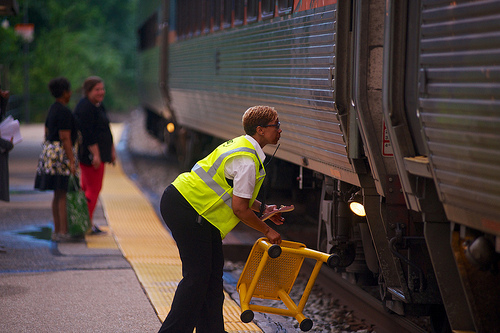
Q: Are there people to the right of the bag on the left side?
A: Yes, there is a person to the right of the bag.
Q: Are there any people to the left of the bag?
A: No, the person is to the right of the bag.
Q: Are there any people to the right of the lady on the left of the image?
A: Yes, there is a person to the right of the lady.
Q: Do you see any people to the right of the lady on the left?
A: Yes, there is a person to the right of the lady.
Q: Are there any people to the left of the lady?
A: No, the person is to the right of the lady.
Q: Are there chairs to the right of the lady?
A: No, there is a person to the right of the lady.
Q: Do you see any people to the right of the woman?
A: Yes, there is a person to the right of the woman.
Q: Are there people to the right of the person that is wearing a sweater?
A: Yes, there is a person to the right of the woman.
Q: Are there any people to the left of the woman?
A: No, the person is to the right of the woman.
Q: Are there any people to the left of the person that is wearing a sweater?
A: No, the person is to the right of the woman.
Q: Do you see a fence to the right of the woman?
A: No, there is a person to the right of the woman.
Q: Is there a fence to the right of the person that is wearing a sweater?
A: No, there is a person to the right of the woman.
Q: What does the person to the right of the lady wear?
A: The person wears a dress.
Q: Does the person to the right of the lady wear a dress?
A: Yes, the person wears a dress.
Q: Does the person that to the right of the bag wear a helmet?
A: No, the person wears a dress.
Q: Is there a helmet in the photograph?
A: No, there are no helmets.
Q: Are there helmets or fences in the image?
A: No, there are no helmets or fences.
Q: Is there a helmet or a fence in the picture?
A: No, there are no helmets or fences.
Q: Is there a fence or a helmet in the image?
A: No, there are no helmets or fences.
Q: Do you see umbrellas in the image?
A: No, there are no umbrellas.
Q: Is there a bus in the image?
A: No, there are no buses.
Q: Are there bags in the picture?
A: Yes, there is a bag.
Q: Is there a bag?
A: Yes, there is a bag.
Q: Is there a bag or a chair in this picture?
A: Yes, there is a bag.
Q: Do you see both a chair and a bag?
A: No, there is a bag but no chairs.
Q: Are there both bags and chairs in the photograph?
A: No, there is a bag but no chairs.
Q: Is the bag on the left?
A: Yes, the bag is on the left of the image.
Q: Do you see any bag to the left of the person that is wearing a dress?
A: Yes, there is a bag to the left of the person.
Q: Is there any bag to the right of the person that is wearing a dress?
A: No, the bag is to the left of the person.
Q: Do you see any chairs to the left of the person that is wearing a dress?
A: No, there is a bag to the left of the person.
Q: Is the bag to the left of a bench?
A: No, the bag is to the left of the person.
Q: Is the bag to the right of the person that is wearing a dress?
A: No, the bag is to the left of the person.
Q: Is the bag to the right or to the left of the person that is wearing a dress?
A: The bag is to the left of the person.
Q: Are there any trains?
A: Yes, there is a train.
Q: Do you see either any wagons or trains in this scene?
A: Yes, there is a train.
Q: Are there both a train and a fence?
A: No, there is a train but no fences.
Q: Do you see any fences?
A: No, there are no fences.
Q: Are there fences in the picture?
A: No, there are no fences.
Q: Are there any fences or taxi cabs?
A: No, there are no fences or taxi cabs.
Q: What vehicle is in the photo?
A: The vehicle is a train.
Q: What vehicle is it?
A: The vehicle is a train.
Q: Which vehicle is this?
A: This is a train.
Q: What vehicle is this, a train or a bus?
A: This is a train.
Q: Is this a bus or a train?
A: This is a train.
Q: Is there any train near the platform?
A: Yes, there is a train near the platform.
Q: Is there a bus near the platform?
A: No, there is a train near the platform.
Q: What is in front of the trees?
A: The train is in front of the trees.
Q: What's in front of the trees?
A: The train is in front of the trees.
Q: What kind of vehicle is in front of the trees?
A: The vehicle is a train.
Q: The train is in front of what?
A: The train is in front of the trees.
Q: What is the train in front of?
A: The train is in front of the trees.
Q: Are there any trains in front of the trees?
A: Yes, there is a train in front of the trees.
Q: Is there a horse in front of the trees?
A: No, there is a train in front of the trees.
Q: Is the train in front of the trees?
A: Yes, the train is in front of the trees.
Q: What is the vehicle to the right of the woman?
A: The vehicle is a train.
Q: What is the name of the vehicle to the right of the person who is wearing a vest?
A: The vehicle is a train.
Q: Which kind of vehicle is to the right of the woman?
A: The vehicle is a train.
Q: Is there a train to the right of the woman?
A: Yes, there is a train to the right of the woman.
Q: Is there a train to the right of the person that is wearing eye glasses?
A: Yes, there is a train to the right of the woman.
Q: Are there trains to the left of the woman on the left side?
A: No, the train is to the right of the woman.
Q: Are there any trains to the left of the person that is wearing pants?
A: No, the train is to the right of the woman.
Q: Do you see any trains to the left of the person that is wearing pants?
A: No, the train is to the right of the woman.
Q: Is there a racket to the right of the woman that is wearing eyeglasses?
A: No, there is a train to the right of the woman.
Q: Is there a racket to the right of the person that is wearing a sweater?
A: No, there is a train to the right of the woman.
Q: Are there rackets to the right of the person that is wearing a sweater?
A: No, there is a train to the right of the woman.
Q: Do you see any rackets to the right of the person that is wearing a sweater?
A: No, there is a train to the right of the woman.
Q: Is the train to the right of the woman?
A: Yes, the train is to the right of the woman.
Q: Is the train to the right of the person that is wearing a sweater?
A: Yes, the train is to the right of the woman.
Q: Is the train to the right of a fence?
A: No, the train is to the right of the woman.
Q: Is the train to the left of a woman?
A: No, the train is to the right of a woman.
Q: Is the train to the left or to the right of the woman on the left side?
A: The train is to the right of the woman.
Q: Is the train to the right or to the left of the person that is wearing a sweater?
A: The train is to the right of the woman.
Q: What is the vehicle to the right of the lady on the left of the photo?
A: The vehicle is a train.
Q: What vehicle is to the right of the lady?
A: The vehicle is a train.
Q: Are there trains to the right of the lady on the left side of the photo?
A: Yes, there is a train to the right of the lady.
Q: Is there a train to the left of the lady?
A: No, the train is to the right of the lady.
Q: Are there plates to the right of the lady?
A: No, there is a train to the right of the lady.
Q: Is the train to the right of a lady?
A: Yes, the train is to the right of a lady.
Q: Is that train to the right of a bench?
A: No, the train is to the right of a lady.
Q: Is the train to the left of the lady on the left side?
A: No, the train is to the right of the lady.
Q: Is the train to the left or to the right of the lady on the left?
A: The train is to the right of the lady.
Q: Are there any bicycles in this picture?
A: No, there are no bicycles.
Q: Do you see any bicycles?
A: No, there are no bicycles.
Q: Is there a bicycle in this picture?
A: No, there are no bicycles.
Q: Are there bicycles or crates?
A: No, there are no bicycles or crates.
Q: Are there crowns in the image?
A: No, there are no crowns.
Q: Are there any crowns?
A: No, there are no crowns.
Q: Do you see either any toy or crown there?
A: No, there are no crowns or toys.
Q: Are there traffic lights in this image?
A: No, there are no traffic lights.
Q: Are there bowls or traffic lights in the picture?
A: No, there are no traffic lights or bowls.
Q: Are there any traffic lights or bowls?
A: No, there are no traffic lights or bowls.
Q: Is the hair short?
A: Yes, the hair is short.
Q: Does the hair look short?
A: Yes, the hair is short.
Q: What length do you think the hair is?
A: The hair is short.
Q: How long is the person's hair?
A: The hair is short.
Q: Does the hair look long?
A: No, the hair is short.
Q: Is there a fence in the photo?
A: No, there are no fences.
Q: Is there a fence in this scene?
A: No, there are no fences.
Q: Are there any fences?
A: No, there are no fences.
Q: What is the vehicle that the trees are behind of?
A: The vehicle is a train.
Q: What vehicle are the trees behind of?
A: The trees are behind the train.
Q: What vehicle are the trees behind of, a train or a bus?
A: The trees are behind a train.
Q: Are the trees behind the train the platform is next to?
A: Yes, the trees are behind the train.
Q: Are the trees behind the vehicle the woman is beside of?
A: Yes, the trees are behind the train.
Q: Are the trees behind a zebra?
A: No, the trees are behind the train.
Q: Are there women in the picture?
A: Yes, there is a woman.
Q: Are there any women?
A: Yes, there is a woman.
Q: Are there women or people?
A: Yes, there is a woman.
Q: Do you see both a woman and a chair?
A: No, there is a woman but no chairs.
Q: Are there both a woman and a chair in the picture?
A: No, there is a woman but no chairs.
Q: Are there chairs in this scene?
A: No, there are no chairs.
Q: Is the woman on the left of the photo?
A: Yes, the woman is on the left of the image.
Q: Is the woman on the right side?
A: No, the woman is on the left of the image.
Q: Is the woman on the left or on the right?
A: The woman is on the left of the image.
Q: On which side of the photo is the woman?
A: The woman is on the left of the image.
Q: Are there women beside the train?
A: Yes, there is a woman beside the train.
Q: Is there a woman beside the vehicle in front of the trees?
A: Yes, there is a woman beside the train.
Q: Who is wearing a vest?
A: The woman is wearing a vest.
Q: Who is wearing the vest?
A: The woman is wearing a vest.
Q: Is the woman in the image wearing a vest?
A: Yes, the woman is wearing a vest.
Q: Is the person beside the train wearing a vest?
A: Yes, the woman is wearing a vest.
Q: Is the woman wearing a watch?
A: No, the woman is wearing a vest.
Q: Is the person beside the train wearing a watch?
A: No, the woman is wearing a vest.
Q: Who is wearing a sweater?
A: The woman is wearing a sweater.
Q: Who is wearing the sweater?
A: The woman is wearing a sweater.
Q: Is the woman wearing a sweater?
A: Yes, the woman is wearing a sweater.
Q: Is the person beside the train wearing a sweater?
A: Yes, the woman is wearing a sweater.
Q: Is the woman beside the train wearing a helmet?
A: No, the woman is wearing a sweater.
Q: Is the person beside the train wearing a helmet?
A: No, the woman is wearing a sweater.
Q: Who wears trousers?
A: The woman wears trousers.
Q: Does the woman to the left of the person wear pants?
A: Yes, the woman wears pants.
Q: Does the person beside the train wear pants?
A: Yes, the woman wears pants.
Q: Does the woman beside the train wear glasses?
A: No, the woman wears pants.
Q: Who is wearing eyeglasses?
A: The woman is wearing eyeglasses.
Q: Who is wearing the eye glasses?
A: The woman is wearing eyeglasses.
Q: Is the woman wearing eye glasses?
A: Yes, the woman is wearing eye glasses.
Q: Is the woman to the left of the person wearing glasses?
A: No, the woman is wearing eye glasses.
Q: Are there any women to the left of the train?
A: Yes, there is a woman to the left of the train.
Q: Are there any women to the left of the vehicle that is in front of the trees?
A: Yes, there is a woman to the left of the train.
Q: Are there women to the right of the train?
A: No, the woman is to the left of the train.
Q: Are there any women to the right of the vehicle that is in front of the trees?
A: No, the woman is to the left of the train.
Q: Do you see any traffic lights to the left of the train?
A: No, there is a woman to the left of the train.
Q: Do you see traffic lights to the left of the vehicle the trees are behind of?
A: No, there is a woman to the left of the train.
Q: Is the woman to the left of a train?
A: Yes, the woman is to the left of a train.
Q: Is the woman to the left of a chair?
A: No, the woman is to the left of a train.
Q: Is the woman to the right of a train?
A: No, the woman is to the left of a train.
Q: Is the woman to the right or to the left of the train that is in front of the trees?
A: The woman is to the left of the train.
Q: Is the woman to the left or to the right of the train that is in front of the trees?
A: The woman is to the left of the train.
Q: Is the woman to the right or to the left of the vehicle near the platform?
A: The woman is to the left of the train.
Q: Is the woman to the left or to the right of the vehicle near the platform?
A: The woman is to the left of the train.